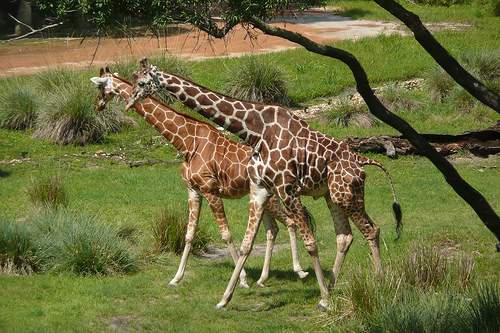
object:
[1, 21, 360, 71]
pond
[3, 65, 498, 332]
grass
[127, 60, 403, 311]
giraffe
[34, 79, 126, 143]
bush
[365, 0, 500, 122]
limb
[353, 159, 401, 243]
tail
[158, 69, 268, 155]
neck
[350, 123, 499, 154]
trunk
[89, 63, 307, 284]
giraffe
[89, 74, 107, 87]
ear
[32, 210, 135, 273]
bush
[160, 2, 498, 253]
limb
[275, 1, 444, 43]
ground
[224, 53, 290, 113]
bush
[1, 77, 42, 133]
bush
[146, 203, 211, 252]
bush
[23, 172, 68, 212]
bush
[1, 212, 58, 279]
bush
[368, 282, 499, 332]
bush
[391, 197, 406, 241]
hair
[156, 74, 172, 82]
nubs